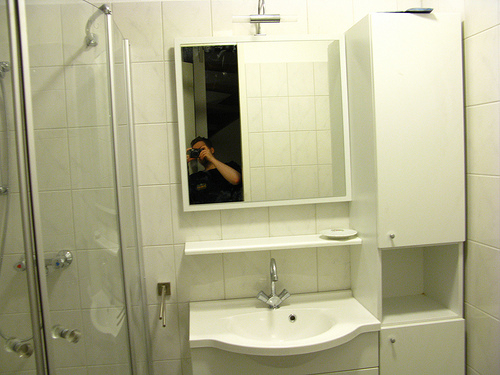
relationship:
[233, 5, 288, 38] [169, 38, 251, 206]
light over mirror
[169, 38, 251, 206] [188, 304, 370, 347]
mirror over sink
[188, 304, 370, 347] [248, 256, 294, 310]
sink has a faucet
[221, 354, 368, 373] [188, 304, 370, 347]
drawer under a sink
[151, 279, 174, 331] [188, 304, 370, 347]
towel rod next to sink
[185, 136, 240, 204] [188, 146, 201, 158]
man holding camera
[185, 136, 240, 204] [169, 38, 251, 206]
man standing in mirror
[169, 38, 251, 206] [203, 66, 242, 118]
mirror has a reflection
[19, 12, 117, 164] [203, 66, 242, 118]
doors has a reflection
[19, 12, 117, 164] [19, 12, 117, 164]
doors made of doors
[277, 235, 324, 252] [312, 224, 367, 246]
counter has a soap dish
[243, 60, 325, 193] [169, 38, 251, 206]
wall reflected in mirror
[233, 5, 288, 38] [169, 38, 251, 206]
light hanging from mirror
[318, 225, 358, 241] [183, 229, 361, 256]
soap on top of counter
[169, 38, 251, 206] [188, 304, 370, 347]
mirror above sink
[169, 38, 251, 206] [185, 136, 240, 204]
mirror has a reflection of man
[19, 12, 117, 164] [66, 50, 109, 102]
doors made of glass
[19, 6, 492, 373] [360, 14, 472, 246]
bathroom has a cupboard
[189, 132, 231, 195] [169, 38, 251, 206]
man in mirror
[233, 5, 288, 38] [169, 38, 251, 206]
light above mirror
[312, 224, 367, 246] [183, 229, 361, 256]
soap dish on top of counter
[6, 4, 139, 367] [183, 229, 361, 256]
shower has a counter